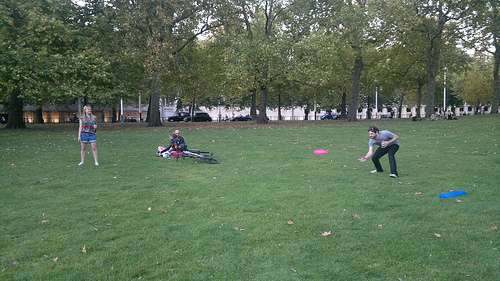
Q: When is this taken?
A: During the daytime.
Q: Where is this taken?
A: In a park.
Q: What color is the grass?
A: Green.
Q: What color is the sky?
A: Blue.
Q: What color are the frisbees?
A: Pink and blue.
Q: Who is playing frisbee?
A: A man and two girls.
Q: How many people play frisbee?
A: Three.